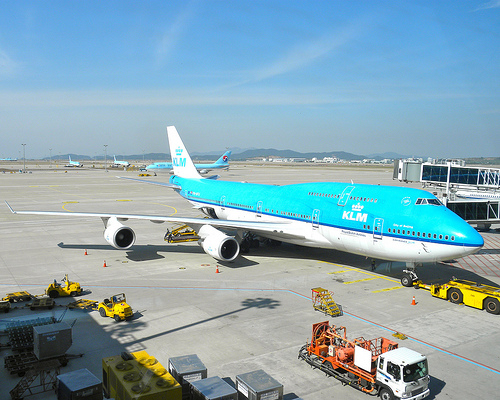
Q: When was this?
A: Daytime.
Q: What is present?
A: A plane.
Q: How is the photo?
A: Clear.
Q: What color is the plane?
A: Blue.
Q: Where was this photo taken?
A: At an airport.